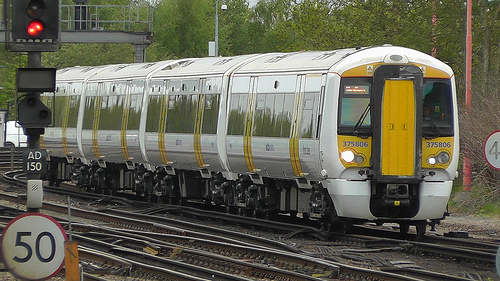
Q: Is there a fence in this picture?
A: No, there are no fences.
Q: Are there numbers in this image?
A: Yes, there are numbers.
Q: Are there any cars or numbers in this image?
A: Yes, there are numbers.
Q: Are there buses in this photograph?
A: No, there are no buses.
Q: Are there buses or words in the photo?
A: No, there are no buses or words.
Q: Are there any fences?
A: No, there are no fences.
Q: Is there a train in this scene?
A: Yes, there is a train.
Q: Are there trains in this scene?
A: Yes, there is a train.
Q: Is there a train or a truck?
A: Yes, there is a train.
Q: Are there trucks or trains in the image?
A: Yes, there is a train.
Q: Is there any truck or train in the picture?
A: Yes, there is a train.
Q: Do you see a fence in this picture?
A: No, there are no fences.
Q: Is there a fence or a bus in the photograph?
A: No, there are no fences or buses.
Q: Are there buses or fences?
A: No, there are no fences or buses.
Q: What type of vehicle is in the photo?
A: The vehicle is a train.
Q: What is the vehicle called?
A: The vehicle is a train.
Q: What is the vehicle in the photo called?
A: The vehicle is a train.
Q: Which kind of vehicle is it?
A: The vehicle is a train.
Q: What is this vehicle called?
A: That is a train.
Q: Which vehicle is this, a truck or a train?
A: That is a train.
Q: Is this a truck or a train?
A: This is a train.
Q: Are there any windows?
A: Yes, there are windows.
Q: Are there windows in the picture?
A: Yes, there are windows.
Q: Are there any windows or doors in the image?
A: Yes, there are windows.